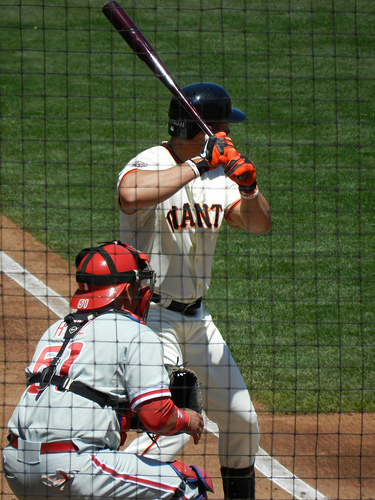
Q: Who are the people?
A: Baseball players.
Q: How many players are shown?
A: Two.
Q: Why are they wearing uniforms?
A: On a team.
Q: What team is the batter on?
A: Giants.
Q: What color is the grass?
A: Green.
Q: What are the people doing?
A: Playing baseball.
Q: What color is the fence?
A: Black.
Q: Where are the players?
A: Baseball field.